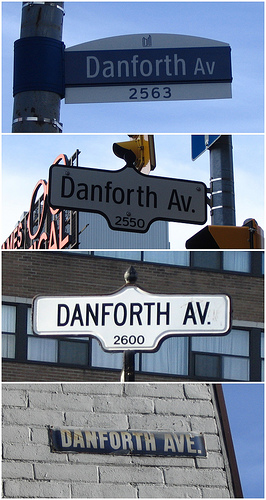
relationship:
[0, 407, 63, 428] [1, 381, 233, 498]
brick on wall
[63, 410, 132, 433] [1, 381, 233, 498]
brick on wall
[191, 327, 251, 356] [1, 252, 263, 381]
window on building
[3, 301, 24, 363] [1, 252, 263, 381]
window on building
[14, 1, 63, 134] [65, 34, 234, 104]
post holding sign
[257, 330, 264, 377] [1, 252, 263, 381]
window on building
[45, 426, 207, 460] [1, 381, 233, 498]
sign on wall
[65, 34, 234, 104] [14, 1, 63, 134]
sign on post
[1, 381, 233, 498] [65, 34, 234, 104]
wall behind sign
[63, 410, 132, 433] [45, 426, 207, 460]
brick above sign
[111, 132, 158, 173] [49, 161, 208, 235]
traffic light above sign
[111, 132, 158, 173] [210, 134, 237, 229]
traffic light attached to pole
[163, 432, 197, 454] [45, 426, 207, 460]
writing on sign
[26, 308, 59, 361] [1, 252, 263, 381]
window on building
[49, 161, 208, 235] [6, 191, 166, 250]
sign in front of building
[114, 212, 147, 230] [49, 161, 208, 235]
number on sign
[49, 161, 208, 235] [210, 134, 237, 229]
sign on pole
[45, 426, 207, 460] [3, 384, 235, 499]
sign on building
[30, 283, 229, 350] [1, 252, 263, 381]
sign in front of building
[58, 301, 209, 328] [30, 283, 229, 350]
writing on sign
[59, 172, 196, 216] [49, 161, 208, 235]
writing on sign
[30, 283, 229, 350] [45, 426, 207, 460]
sign above sign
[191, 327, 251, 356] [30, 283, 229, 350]
window behind sign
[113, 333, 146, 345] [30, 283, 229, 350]
number on sign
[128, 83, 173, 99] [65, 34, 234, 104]
number on sign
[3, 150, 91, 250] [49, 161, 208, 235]
sign behind sign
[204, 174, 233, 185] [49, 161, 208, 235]
brace holding sign